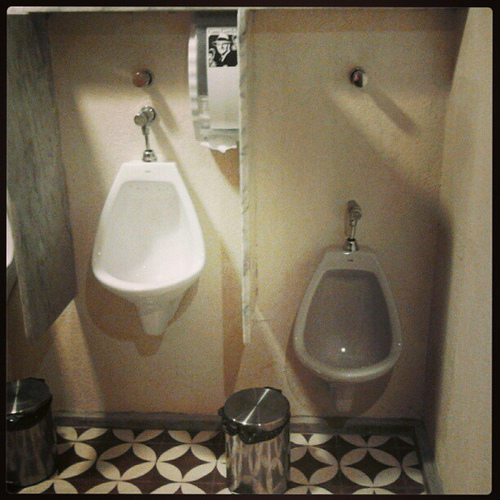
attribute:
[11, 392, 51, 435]
bag — garbage , black 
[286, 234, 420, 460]
urinal — one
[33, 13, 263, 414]
wall — one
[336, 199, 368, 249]
pipe — silver 